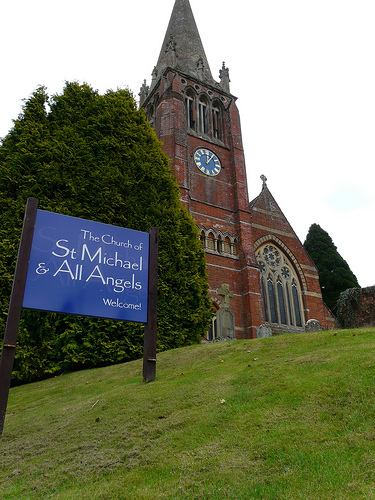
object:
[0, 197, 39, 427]
poles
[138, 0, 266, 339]
churchandtower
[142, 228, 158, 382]
wooden post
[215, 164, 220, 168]
numbers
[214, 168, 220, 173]
numbers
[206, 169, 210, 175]
numbers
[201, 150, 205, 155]
numbers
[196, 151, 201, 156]
numbers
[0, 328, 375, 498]
grass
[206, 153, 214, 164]
hands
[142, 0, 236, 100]
roof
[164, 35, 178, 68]
statue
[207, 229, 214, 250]
window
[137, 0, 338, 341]
building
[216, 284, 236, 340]
tombstone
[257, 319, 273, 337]
tombstone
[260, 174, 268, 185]
cross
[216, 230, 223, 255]
window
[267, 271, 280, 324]
window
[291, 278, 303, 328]
window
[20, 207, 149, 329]
sign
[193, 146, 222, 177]
clock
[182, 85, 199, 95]
arches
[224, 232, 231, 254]
window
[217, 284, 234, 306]
cross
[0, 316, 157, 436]
sign base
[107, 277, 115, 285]
letters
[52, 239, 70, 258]
letter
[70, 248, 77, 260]
letter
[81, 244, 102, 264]
letter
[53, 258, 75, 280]
letter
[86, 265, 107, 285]
letter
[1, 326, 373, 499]
hill